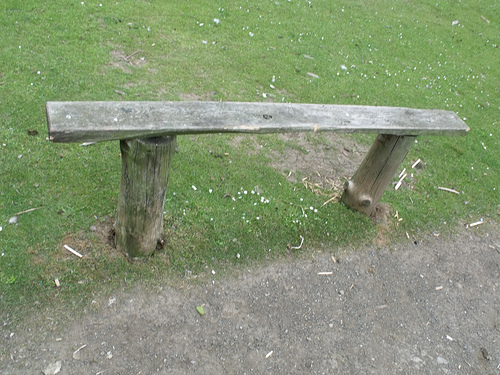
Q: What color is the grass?
A: Green.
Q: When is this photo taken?
A: Daytime.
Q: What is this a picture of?
A: A bench.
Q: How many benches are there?
A: One.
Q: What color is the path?
A: Gray.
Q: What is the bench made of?
A: Wood.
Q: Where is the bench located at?
A: Beside the gravel path.